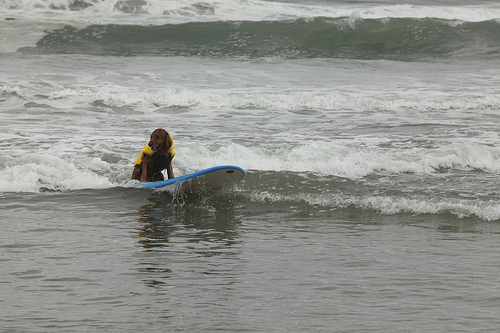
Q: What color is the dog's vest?
A: Yellow.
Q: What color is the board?
A: Blue and white.